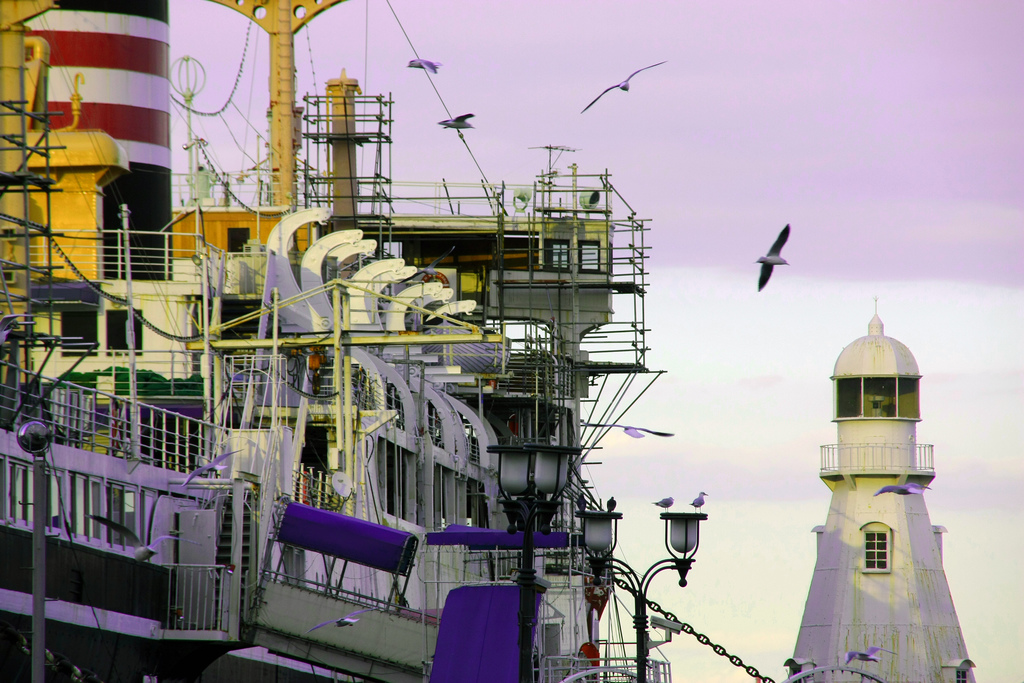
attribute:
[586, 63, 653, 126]
bird — flying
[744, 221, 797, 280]
bird — flying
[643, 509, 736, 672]
light — old-fashioned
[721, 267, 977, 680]
lighthouse — white, yellow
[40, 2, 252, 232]
smokestack — black, white, red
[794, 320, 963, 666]
light house — white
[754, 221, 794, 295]
bird — flying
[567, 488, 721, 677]
pole — light 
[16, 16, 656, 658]
ship — large, superstructure, big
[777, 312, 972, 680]
lighthouse — white 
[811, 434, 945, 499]
walkway — upper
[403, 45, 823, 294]
seagulls — four, flying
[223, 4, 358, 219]
tower — yellow, metal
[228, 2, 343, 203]
tower — metal, yellow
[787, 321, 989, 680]
lighthouse — white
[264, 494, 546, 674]
entrance — purple